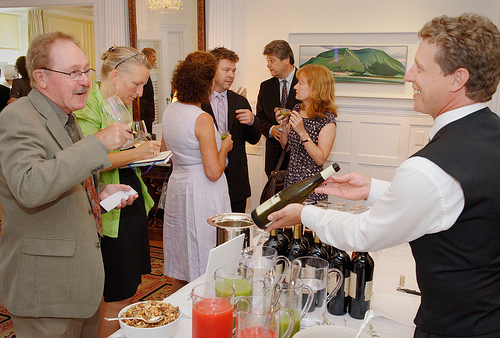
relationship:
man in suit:
[3, 26, 138, 336] [2, 88, 129, 335]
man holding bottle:
[264, 13, 499, 337] [283, 171, 333, 206]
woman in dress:
[159, 48, 234, 285] [160, 98, 234, 283]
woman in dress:
[274, 62, 341, 205] [284, 102, 339, 202]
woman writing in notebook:
[79, 45, 166, 337] [124, 149, 174, 166]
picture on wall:
[298, 42, 408, 96] [237, 4, 389, 27]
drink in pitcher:
[189, 298, 234, 336] [187, 280, 252, 332]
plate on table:
[114, 141, 498, 333] [139, 165, 456, 332]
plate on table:
[114, 141, 498, 333] [376, 295, 408, 311]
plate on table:
[114, 141, 498, 333] [175, 237, 428, 330]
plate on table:
[114, 141, 498, 333] [89, 199, 494, 334]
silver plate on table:
[207, 210, 254, 262] [108, 205, 425, 337]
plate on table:
[114, 141, 498, 333] [108, 205, 425, 337]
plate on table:
[114, 141, 498, 333] [108, 235, 416, 336]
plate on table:
[213, 141, 497, 328] [108, 235, 416, 336]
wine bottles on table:
[305, 231, 373, 319] [377, 252, 415, 325]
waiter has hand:
[399, 11, 498, 333] [262, 201, 303, 236]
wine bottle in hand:
[247, 174, 327, 229] [262, 201, 303, 236]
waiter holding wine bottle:
[399, 11, 498, 333] [247, 174, 327, 229]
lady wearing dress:
[162, 48, 244, 280] [155, 106, 232, 277]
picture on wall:
[298, 42, 408, 92] [239, 0, 499, 212]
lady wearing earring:
[69, 43, 163, 330] [104, 84, 120, 99]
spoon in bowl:
[103, 315, 166, 324] [112, 297, 179, 336]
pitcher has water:
[293, 251, 338, 321] [313, 297, 323, 315]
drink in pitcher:
[189, 283, 235, 336] [190, 281, 237, 336]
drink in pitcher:
[216, 279, 246, 294] [198, 259, 260, 318]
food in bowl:
[121, 301, 179, 326] [115, 294, 188, 333]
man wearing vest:
[264, 13, 499, 337] [405, 106, 498, 336]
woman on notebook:
[79, 45, 155, 337] [128, 142, 174, 169]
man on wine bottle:
[264, 13, 499, 337] [251, 162, 342, 229]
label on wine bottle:
[256, 191, 281, 216] [251, 162, 342, 229]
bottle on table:
[348, 247, 372, 318] [108, 235, 416, 336]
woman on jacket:
[79, 45, 166, 337] [75, 82, 160, 246]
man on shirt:
[264, 13, 499, 337] [390, 162, 453, 238]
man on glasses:
[3, 26, 138, 336] [44, 59, 96, 81]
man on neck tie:
[0, 32, 122, 335] [67, 113, 110, 234]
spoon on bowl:
[99, 311, 164, 326] [116, 297, 181, 337]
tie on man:
[274, 77, 292, 108] [255, 37, 295, 187]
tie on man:
[62, 108, 107, 226] [208, 43, 256, 217]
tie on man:
[62, 108, 107, 226] [0, 31, 107, 335]